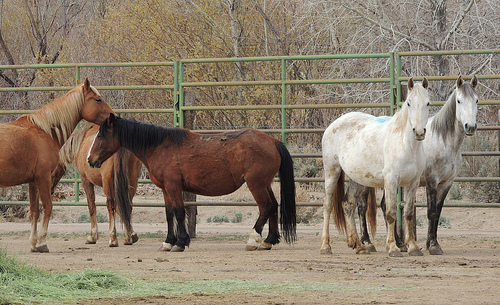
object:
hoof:
[241, 236, 262, 252]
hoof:
[254, 238, 273, 251]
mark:
[389, 124, 413, 137]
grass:
[0, 242, 421, 304]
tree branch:
[188, 0, 232, 40]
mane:
[112, 115, 189, 156]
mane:
[25, 82, 86, 148]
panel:
[0, 73, 123, 254]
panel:
[309, 69, 439, 265]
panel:
[383, 75, 481, 258]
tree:
[283, 0, 498, 144]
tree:
[0, 0, 85, 116]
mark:
[374, 114, 393, 124]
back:
[320, 110, 405, 131]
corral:
[0, 48, 499, 305]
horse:
[357, 73, 481, 256]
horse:
[50, 122, 143, 247]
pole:
[179, 105, 285, 111]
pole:
[280, 51, 392, 60]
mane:
[17, 81, 109, 150]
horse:
[0, 76, 116, 256]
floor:
[0, 197, 499, 304]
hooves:
[155, 241, 175, 254]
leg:
[163, 181, 191, 245]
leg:
[317, 163, 342, 257]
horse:
[315, 76, 432, 258]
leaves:
[162, 23, 182, 38]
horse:
[83, 111, 299, 253]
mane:
[429, 90, 457, 150]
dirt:
[0, 222, 499, 304]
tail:
[272, 137, 296, 247]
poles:
[181, 54, 281, 62]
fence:
[0, 47, 498, 208]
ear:
[405, 76, 414, 91]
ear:
[419, 76, 430, 91]